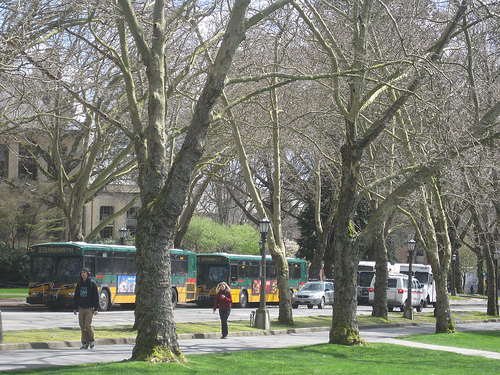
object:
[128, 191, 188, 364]
tree trunk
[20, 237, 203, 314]
bus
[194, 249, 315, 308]
bus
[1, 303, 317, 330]
street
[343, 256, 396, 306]
van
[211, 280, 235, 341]
people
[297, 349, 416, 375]
grass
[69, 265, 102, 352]
man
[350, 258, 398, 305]
bus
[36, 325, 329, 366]
sidewalk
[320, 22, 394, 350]
tree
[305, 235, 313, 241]
leaves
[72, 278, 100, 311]
jacket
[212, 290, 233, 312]
jacket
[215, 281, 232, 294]
hair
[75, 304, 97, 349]
pants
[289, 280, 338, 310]
car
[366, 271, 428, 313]
van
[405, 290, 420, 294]
stripe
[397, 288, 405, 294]
light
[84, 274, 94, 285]
hoodie